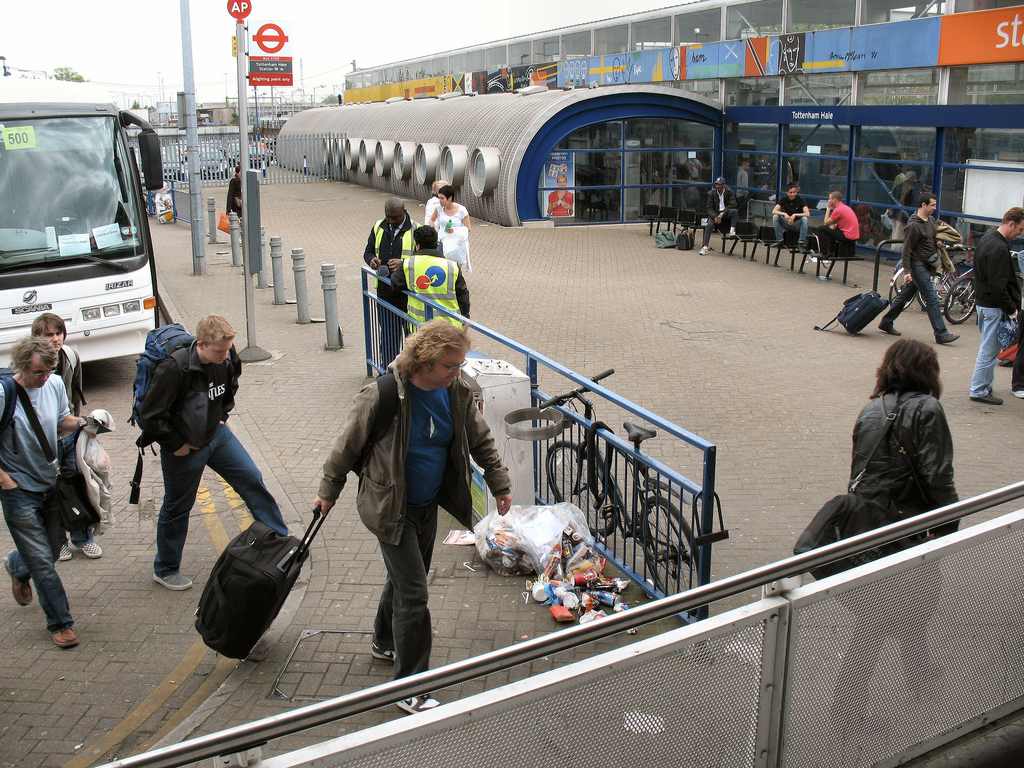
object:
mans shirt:
[403, 378, 455, 511]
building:
[275, 83, 724, 226]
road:
[0, 180, 1024, 768]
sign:
[245, 17, 301, 91]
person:
[0, 336, 101, 646]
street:
[0, 353, 251, 768]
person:
[29, 313, 104, 559]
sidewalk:
[156, 176, 1024, 752]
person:
[823, 336, 962, 736]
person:
[966, 207, 1024, 403]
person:
[877, 193, 958, 346]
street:
[0, 352, 267, 768]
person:
[429, 185, 474, 275]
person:
[362, 197, 424, 369]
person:
[390, 224, 472, 335]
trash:
[527, 528, 632, 625]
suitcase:
[193, 514, 310, 662]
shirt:
[207, 362, 230, 447]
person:
[139, 311, 291, 592]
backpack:
[125, 322, 197, 431]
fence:
[357, 262, 716, 625]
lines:
[63, 475, 230, 767]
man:
[305, 316, 516, 713]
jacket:
[315, 367, 512, 544]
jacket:
[133, 338, 243, 461]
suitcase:
[836, 291, 888, 335]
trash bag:
[470, 501, 595, 577]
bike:
[535, 364, 711, 616]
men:
[807, 189, 859, 262]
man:
[697, 174, 742, 256]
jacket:
[706, 185, 740, 235]